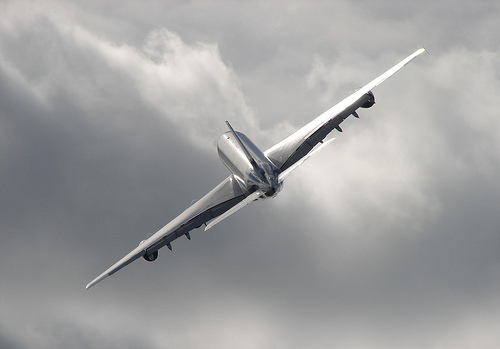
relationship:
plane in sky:
[82, 40, 425, 290] [0, 0, 498, 347]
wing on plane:
[52, 171, 256, 311] [72, 6, 433, 303]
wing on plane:
[261, 45, 426, 168] [25, 32, 450, 299]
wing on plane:
[202, 191, 254, 237] [82, 40, 425, 290]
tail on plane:
[248, 162, 283, 193] [147, 120, 362, 259]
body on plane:
[215, 128, 281, 200] [82, 40, 425, 290]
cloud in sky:
[0, 1, 500, 349] [0, 0, 498, 347]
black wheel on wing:
[363, 90, 376, 109] [295, 56, 455, 171]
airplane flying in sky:
[78, 33, 459, 299] [0, 0, 498, 347]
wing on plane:
[83, 168, 262, 309] [82, 40, 425, 290]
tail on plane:
[213, 110, 291, 206] [82, 40, 425, 290]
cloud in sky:
[84, 18, 261, 138] [0, 0, 498, 347]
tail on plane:
[225, 121, 268, 182] [82, 40, 425, 290]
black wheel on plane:
[363, 90, 377, 110] [82, 40, 425, 290]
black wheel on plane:
[144, 249, 159, 263] [82, 40, 425, 290]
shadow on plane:
[200, 155, 250, 185] [9, 22, 453, 340]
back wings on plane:
[200, 134, 334, 228] [82, 40, 425, 290]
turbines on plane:
[356, 88, 374, 110] [82, 40, 425, 290]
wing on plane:
[261, 45, 426, 168] [82, 40, 425, 290]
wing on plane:
[83, 173, 240, 288] [82, 40, 425, 290]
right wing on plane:
[257, 49, 427, 169] [58, 42, 448, 305]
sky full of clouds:
[0, 0, 498, 347] [0, 1, 255, 171]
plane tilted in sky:
[82, 40, 425, 290] [0, 0, 498, 347]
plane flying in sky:
[82, 40, 425, 290] [0, 0, 498, 347]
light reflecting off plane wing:
[266, 45, 427, 154] [260, 41, 429, 172]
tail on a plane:
[204, 125, 330, 238] [60, 18, 487, 293]